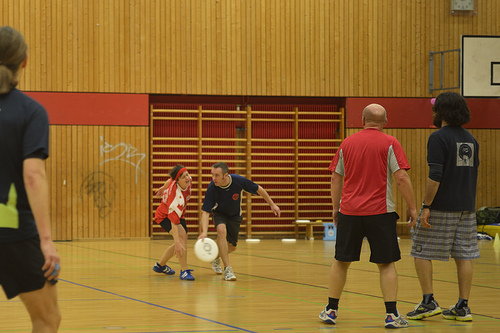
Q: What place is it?
A: It is a gym.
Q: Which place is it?
A: It is a gym.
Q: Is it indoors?
A: Yes, it is indoors.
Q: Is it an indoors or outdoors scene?
A: It is indoors.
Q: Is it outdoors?
A: No, it is indoors.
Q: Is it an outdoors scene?
A: No, it is indoors.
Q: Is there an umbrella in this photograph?
A: No, there are no umbrellas.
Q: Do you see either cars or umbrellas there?
A: No, there are no umbrellas or cars.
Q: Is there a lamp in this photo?
A: No, there are no lamps.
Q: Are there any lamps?
A: No, there are no lamps.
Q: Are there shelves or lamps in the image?
A: No, there are no lamps or shelves.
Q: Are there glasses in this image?
A: No, there are no glasses.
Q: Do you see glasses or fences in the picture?
A: No, there are no glasses or fences.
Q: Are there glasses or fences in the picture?
A: No, there are no glasses or fences.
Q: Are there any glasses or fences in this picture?
A: No, there are no glasses or fences.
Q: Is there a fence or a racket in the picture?
A: No, there are no fences or rackets.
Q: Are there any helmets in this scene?
A: No, there are no helmets.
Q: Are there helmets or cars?
A: No, there are no helmets or cars.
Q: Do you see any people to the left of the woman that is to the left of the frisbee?
A: Yes, there is a person to the left of the woman.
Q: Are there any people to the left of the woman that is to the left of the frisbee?
A: Yes, there is a person to the left of the woman.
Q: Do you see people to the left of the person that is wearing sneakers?
A: Yes, there is a person to the left of the woman.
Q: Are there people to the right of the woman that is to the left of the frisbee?
A: No, the person is to the left of the woman.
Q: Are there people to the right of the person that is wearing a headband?
A: No, the person is to the left of the woman.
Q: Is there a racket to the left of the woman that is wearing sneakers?
A: No, there is a person to the left of the woman.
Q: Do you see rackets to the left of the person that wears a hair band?
A: No, there is a person to the left of the woman.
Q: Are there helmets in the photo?
A: No, there are no helmets.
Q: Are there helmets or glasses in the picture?
A: No, there are no helmets or glasses.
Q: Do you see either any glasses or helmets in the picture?
A: No, there are no helmets or glasses.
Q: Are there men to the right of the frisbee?
A: Yes, there is a man to the right of the frisbee.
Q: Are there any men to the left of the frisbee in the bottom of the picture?
A: No, the man is to the right of the frisbee.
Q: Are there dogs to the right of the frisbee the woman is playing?
A: No, there is a man to the right of the frisbee.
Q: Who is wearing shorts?
A: The man is wearing shorts.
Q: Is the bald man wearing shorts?
A: Yes, the man is wearing shorts.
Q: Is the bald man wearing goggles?
A: No, the man is wearing shorts.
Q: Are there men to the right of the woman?
A: Yes, there is a man to the right of the woman.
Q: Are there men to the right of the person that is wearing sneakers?
A: Yes, there is a man to the right of the woman.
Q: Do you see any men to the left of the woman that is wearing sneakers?
A: No, the man is to the right of the woman.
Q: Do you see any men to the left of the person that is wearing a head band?
A: No, the man is to the right of the woman.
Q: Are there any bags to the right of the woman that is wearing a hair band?
A: No, there is a man to the right of the woman.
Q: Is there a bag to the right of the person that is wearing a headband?
A: No, there is a man to the right of the woman.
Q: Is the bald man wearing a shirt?
A: Yes, the man is wearing a shirt.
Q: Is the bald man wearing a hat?
A: No, the man is wearing a shirt.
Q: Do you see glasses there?
A: No, there are no glasses.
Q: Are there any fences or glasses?
A: No, there are no glasses or fences.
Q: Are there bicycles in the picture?
A: No, there are no bicycles.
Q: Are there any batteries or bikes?
A: No, there are no bikes or batteries.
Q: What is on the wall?
A: The graffiti is on the wall.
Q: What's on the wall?
A: The graffiti is on the wall.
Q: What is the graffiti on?
A: The graffiti is on the wall.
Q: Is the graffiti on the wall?
A: Yes, the graffiti is on the wall.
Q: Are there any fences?
A: No, there are no fences.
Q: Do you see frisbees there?
A: Yes, there is a frisbee.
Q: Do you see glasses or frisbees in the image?
A: Yes, there is a frisbee.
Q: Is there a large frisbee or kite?
A: Yes, there is a large frisbee.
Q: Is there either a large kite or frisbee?
A: Yes, there is a large frisbee.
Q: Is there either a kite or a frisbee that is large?
A: Yes, the frisbee is large.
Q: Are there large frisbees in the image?
A: Yes, there is a large frisbee.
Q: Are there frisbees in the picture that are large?
A: Yes, there is a frisbee that is large.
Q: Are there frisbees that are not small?
A: Yes, there is a large frisbee.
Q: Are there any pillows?
A: No, there are no pillows.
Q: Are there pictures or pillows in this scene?
A: No, there are no pillows or pictures.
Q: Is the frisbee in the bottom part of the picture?
A: Yes, the frisbee is in the bottom of the image.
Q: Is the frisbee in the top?
A: No, the frisbee is in the bottom of the image.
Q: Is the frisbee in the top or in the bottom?
A: The frisbee is in the bottom of the image.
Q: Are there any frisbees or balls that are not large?
A: No, there is a frisbee but it is large.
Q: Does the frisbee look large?
A: Yes, the frisbee is large.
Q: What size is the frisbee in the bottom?
A: The frisbee is large.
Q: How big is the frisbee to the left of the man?
A: The frisbee is large.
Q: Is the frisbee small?
A: No, the frisbee is large.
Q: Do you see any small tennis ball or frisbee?
A: No, there is a frisbee but it is large.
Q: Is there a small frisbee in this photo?
A: No, there is a frisbee but it is large.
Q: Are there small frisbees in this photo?
A: No, there is a frisbee but it is large.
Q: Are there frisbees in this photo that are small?
A: No, there is a frisbee but it is large.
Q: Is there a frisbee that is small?
A: No, there is a frisbee but it is large.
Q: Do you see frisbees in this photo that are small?
A: No, there is a frisbee but it is large.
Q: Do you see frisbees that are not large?
A: No, there is a frisbee but it is large.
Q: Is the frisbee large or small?
A: The frisbee is large.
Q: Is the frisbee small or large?
A: The frisbee is large.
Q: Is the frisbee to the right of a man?
A: No, the frisbee is to the left of a man.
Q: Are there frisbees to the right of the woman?
A: Yes, there is a frisbee to the right of the woman.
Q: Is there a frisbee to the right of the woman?
A: Yes, there is a frisbee to the right of the woman.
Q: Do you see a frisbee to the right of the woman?
A: Yes, there is a frisbee to the right of the woman.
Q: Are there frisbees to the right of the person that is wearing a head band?
A: Yes, there is a frisbee to the right of the woman.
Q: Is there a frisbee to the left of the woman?
A: No, the frisbee is to the right of the woman.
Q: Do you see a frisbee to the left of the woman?
A: No, the frisbee is to the right of the woman.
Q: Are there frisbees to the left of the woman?
A: No, the frisbee is to the right of the woman.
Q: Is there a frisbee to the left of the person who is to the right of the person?
A: No, the frisbee is to the right of the woman.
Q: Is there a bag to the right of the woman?
A: No, there is a frisbee to the right of the woman.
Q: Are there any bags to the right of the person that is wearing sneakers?
A: No, there is a frisbee to the right of the woman.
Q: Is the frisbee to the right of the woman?
A: Yes, the frisbee is to the right of the woman.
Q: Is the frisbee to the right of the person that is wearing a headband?
A: Yes, the frisbee is to the right of the woman.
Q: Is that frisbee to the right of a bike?
A: No, the frisbee is to the right of the woman.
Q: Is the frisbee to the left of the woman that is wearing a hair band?
A: No, the frisbee is to the right of the woman.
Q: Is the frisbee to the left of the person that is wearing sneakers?
A: No, the frisbee is to the right of the woman.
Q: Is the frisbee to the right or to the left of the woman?
A: The frisbee is to the right of the woman.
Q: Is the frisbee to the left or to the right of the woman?
A: The frisbee is to the right of the woman.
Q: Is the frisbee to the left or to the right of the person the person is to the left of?
A: The frisbee is to the right of the woman.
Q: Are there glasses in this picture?
A: No, there are no glasses.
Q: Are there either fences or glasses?
A: No, there are no glasses or fences.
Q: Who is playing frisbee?
A: The man is playing frisbee.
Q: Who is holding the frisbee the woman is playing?
A: The man is holding the frisbee.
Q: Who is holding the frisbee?
A: The man is holding the frisbee.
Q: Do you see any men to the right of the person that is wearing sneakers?
A: Yes, there is a man to the right of the woman.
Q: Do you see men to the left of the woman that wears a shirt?
A: No, the man is to the right of the woman.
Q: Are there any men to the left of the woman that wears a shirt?
A: No, the man is to the right of the woman.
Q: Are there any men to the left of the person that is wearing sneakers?
A: No, the man is to the right of the woman.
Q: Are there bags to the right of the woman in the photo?
A: No, there is a man to the right of the woman.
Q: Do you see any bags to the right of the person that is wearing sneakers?
A: No, there is a man to the right of the woman.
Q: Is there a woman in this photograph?
A: Yes, there is a woman.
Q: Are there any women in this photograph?
A: Yes, there is a woman.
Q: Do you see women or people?
A: Yes, there is a woman.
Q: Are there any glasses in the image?
A: No, there are no glasses.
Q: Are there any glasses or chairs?
A: No, there are no glasses or chairs.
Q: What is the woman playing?
A: The woman is playing frisbee.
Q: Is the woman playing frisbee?
A: Yes, the woman is playing frisbee.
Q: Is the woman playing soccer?
A: No, the woman is playing frisbee.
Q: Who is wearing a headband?
A: The woman is wearing a headband.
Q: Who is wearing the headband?
A: The woman is wearing a headband.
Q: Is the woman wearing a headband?
A: Yes, the woman is wearing a headband.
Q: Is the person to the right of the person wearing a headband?
A: Yes, the woman is wearing a headband.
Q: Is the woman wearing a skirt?
A: No, the woman is wearing a headband.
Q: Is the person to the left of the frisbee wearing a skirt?
A: No, the woman is wearing a headband.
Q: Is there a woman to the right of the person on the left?
A: Yes, there is a woman to the right of the person.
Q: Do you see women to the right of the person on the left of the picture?
A: Yes, there is a woman to the right of the person.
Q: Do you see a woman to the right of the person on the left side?
A: Yes, there is a woman to the right of the person.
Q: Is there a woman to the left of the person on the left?
A: No, the woman is to the right of the person.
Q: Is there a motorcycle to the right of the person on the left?
A: No, there is a woman to the right of the person.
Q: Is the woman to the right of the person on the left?
A: Yes, the woman is to the right of the person.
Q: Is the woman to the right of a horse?
A: No, the woman is to the right of the person.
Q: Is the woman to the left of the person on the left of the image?
A: No, the woman is to the right of the person.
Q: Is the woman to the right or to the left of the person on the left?
A: The woman is to the right of the person.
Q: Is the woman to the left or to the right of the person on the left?
A: The woman is to the right of the person.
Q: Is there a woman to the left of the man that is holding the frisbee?
A: Yes, there is a woman to the left of the man.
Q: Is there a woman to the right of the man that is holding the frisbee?
A: No, the woman is to the left of the man.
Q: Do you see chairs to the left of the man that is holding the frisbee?
A: No, there is a woman to the left of the man.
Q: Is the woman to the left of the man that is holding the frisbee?
A: Yes, the woman is to the left of the man.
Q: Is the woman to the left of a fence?
A: No, the woman is to the left of the man.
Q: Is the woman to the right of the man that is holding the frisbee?
A: No, the woman is to the left of the man.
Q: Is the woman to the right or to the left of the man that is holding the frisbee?
A: The woman is to the left of the man.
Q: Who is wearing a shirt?
A: The woman is wearing a shirt.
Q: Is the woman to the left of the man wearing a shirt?
A: Yes, the woman is wearing a shirt.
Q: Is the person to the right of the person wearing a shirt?
A: Yes, the woman is wearing a shirt.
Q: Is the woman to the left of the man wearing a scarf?
A: No, the woman is wearing a shirt.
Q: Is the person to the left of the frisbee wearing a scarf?
A: No, the woman is wearing a shirt.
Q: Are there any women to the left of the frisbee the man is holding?
A: Yes, there is a woman to the left of the frisbee.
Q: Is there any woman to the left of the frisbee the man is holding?
A: Yes, there is a woman to the left of the frisbee.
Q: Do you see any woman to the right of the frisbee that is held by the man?
A: No, the woman is to the left of the frisbee.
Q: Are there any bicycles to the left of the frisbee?
A: No, there is a woman to the left of the frisbee.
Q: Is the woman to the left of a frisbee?
A: Yes, the woman is to the left of a frisbee.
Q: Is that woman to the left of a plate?
A: No, the woman is to the left of a frisbee.